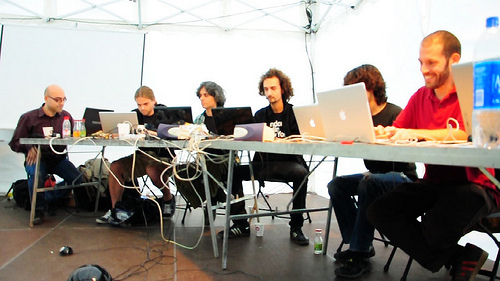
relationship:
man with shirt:
[364, 30, 499, 281] [387, 83, 498, 194]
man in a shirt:
[324, 63, 421, 280] [362, 102, 419, 182]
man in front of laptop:
[324, 63, 421, 280] [290, 101, 337, 145]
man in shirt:
[215, 66, 310, 247] [252, 101, 314, 176]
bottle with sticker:
[470, 13, 499, 152] [472, 59, 500, 110]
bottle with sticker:
[80, 119, 89, 139] [82, 128, 88, 140]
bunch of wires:
[48, 131, 233, 279] [46, 130, 208, 178]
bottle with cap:
[61, 113, 73, 140] [64, 115, 71, 121]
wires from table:
[46, 130, 208, 178] [18, 131, 499, 270]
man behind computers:
[364, 30, 499, 281] [314, 80, 411, 143]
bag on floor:
[2, 178, 55, 212] [1, 189, 500, 280]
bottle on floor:
[313, 228, 326, 256] [1, 189, 500, 280]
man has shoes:
[215, 66, 310, 247] [215, 214, 312, 245]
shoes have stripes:
[215, 214, 312, 245] [230, 227, 247, 237]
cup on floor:
[254, 221, 266, 238] [1, 189, 500, 280]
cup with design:
[254, 221, 266, 238] [256, 226, 262, 231]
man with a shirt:
[364, 30, 499, 281] [387, 83, 498, 194]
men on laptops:
[10, 28, 492, 138] [80, 58, 493, 137]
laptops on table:
[80, 58, 493, 137] [18, 131, 499, 270]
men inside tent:
[10, 28, 492, 138] [5, 0, 493, 206]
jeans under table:
[327, 168, 413, 252] [18, 131, 499, 270]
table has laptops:
[18, 131, 499, 270] [80, 58, 493, 137]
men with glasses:
[10, 88, 96, 223] [46, 94, 69, 103]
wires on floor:
[53, 209, 250, 280] [1, 189, 500, 280]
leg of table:
[215, 151, 241, 275] [18, 131, 499, 270]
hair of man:
[257, 66, 296, 102] [215, 66, 310, 247]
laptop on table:
[210, 107, 256, 141] [18, 131, 499, 270]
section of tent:
[1, 15, 152, 145] [5, 0, 493, 206]